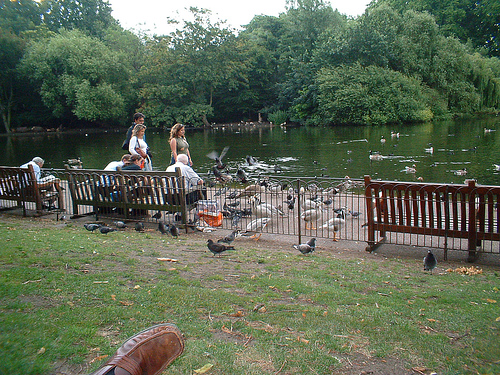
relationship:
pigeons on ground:
[194, 205, 336, 275] [88, 240, 380, 357]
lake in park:
[8, 122, 498, 188] [5, 177, 498, 370]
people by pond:
[108, 110, 205, 187] [291, 131, 329, 161]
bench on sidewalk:
[360, 174, 498, 259] [1, 179, 498, 263]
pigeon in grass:
[203, 236, 238, 258] [0, 213, 490, 373]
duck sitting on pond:
[368, 148, 380, 155] [0, 117, 498, 195]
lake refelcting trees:
[8, 122, 498, 188] [15, 5, 473, 132]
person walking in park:
[166, 123, 191, 164] [3, 2, 483, 372]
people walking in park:
[128, 123, 151, 172] [3, 2, 483, 372]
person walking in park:
[122, 109, 145, 153] [3, 2, 483, 372]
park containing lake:
[3, 2, 483, 372] [8, 122, 498, 188]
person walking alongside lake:
[166, 123, 191, 164] [8, 122, 498, 188]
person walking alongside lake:
[123, 122, 152, 171] [8, 122, 498, 188]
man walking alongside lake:
[162, 154, 208, 208] [8, 122, 498, 188]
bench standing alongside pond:
[63, 165, 207, 232] [2, 110, 484, 204]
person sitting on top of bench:
[92, 153, 130, 197] [63, 165, 207, 232]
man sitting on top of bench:
[162, 154, 208, 208] [63, 165, 207, 232]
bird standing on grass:
[290, 233, 318, 258] [0, 213, 490, 373]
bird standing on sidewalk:
[312, 210, 350, 239] [2, 173, 484, 254]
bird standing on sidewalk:
[297, 201, 327, 232] [2, 173, 484, 254]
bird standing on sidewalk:
[247, 194, 284, 220] [2, 173, 484, 254]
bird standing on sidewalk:
[279, 187, 299, 211] [2, 173, 484, 254]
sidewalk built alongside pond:
[2, 173, 484, 254] [2, 110, 484, 204]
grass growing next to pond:
[0, 213, 490, 373] [2, 110, 484, 204]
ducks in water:
[339, 124, 494, 178] [0, 89, 499, 190]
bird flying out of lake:
[207, 145, 233, 170] [8, 122, 498, 188]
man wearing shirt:
[162, 154, 208, 208] [165, 160, 198, 190]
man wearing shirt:
[162, 154, 208, 208] [159, 154, 207, 203]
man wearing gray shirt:
[99, 152, 133, 194] [102, 158, 122, 173]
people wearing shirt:
[128, 123, 151, 172] [172, 135, 187, 154]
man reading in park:
[16, 153, 59, 192] [3, 114, 493, 374]